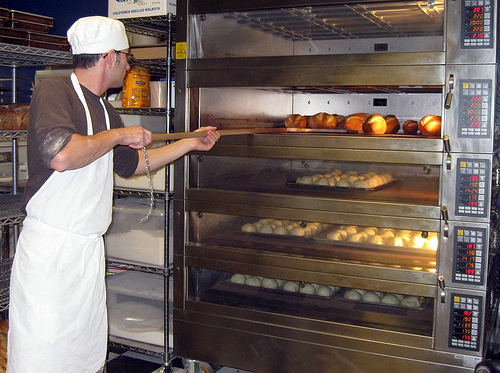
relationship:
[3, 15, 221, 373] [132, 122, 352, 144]
chef holding stick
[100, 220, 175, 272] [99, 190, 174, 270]
flour in container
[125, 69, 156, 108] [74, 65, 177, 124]
orange bag on rack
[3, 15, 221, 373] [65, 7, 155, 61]
chef wearing hat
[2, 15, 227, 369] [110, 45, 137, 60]
chef wearing glasses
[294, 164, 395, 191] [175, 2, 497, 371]
bread dough cooking in oven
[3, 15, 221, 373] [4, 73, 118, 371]
chef wearing apron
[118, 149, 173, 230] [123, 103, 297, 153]
chain hanging from stick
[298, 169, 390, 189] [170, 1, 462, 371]
dough in oven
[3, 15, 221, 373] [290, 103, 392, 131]
chef getting bread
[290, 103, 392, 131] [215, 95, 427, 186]
bread in oven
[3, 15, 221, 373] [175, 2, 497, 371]
chef in front of oven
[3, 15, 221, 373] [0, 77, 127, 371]
chef wearing apron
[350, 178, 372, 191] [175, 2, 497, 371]
bread dough in oven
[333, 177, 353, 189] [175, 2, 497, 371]
dough in oven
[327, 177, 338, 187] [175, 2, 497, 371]
uncooked bread in oven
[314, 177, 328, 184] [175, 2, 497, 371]
uncooked bread in oven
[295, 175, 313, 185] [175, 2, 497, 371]
uncooked bread in oven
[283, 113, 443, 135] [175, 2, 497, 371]
bread in oven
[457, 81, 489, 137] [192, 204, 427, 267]
control panel on oven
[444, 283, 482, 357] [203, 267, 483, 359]
control panel on oven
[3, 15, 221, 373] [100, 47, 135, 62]
chef wearing glasses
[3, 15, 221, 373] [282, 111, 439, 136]
chef getting bread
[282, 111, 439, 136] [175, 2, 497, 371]
bread in oven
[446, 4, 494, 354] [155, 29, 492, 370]
numbers on ovens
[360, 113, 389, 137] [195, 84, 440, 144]
bread on rack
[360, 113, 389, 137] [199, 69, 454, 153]
bread in oven